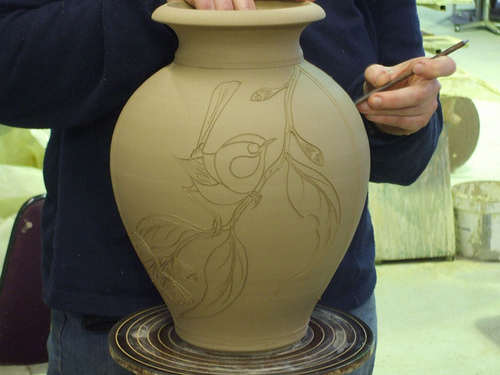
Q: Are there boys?
A: No, there are no boys.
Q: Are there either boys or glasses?
A: No, there are no boys or glasses.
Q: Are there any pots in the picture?
A: Yes, there is a pot.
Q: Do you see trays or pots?
A: Yes, there is a pot.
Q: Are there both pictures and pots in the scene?
A: No, there is a pot but no pictures.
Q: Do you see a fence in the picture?
A: No, there are no fences.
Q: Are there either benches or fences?
A: No, there are no fences or benches.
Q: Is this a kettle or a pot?
A: This is a pot.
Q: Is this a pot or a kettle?
A: This is a pot.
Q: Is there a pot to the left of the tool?
A: Yes, there is a pot to the left of the tool.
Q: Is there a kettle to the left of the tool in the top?
A: No, there is a pot to the left of the tool.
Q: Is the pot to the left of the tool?
A: Yes, the pot is to the left of the tool.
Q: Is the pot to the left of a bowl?
A: No, the pot is to the left of the tool.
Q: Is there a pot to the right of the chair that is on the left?
A: Yes, there is a pot to the right of the chair.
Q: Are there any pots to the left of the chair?
A: No, the pot is to the right of the chair.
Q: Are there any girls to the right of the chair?
A: No, there is a pot to the right of the chair.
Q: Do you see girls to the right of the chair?
A: No, there is a pot to the right of the chair.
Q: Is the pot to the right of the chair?
A: Yes, the pot is to the right of the chair.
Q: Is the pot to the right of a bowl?
A: No, the pot is to the right of the chair.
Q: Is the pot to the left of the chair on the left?
A: No, the pot is to the right of the chair.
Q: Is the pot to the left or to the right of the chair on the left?
A: The pot is to the right of the chair.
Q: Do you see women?
A: No, there are no women.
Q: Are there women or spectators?
A: No, there are no women or spectators.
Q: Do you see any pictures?
A: No, there are no pictures.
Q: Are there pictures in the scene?
A: No, there are no pictures.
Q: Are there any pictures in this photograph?
A: No, there are no pictures.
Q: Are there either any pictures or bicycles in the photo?
A: No, there are no pictures or bicycles.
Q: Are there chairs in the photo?
A: Yes, there is a chair.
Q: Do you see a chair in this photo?
A: Yes, there is a chair.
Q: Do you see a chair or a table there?
A: Yes, there is a chair.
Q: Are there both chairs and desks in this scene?
A: No, there is a chair but no desks.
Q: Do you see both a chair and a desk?
A: No, there is a chair but no desks.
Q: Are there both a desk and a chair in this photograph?
A: No, there is a chair but no desks.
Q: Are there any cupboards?
A: No, there are no cupboards.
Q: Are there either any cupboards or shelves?
A: No, there are no cupboards or shelves.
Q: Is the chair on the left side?
A: Yes, the chair is on the left of the image.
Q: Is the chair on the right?
A: No, the chair is on the left of the image.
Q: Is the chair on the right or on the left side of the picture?
A: The chair is on the left of the image.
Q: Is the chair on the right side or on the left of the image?
A: The chair is on the left of the image.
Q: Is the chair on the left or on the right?
A: The chair is on the left of the image.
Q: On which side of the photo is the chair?
A: The chair is on the left of the image.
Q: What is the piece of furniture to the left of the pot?
A: The piece of furniture is a chair.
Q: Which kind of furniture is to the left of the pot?
A: The piece of furniture is a chair.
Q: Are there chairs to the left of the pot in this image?
A: Yes, there is a chair to the left of the pot.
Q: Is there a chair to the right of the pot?
A: No, the chair is to the left of the pot.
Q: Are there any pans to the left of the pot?
A: No, there is a chair to the left of the pot.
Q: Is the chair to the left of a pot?
A: Yes, the chair is to the left of a pot.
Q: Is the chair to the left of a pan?
A: No, the chair is to the left of a pot.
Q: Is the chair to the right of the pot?
A: No, the chair is to the left of the pot.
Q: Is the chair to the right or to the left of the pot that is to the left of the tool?
A: The chair is to the left of the pot.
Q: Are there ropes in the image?
A: No, there are no ropes.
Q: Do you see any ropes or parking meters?
A: No, there are no ropes or parking meters.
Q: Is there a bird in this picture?
A: Yes, there is a bird.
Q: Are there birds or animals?
A: Yes, there is a bird.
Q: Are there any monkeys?
A: No, there are no monkeys.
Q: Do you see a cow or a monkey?
A: No, there are no monkeys or cows.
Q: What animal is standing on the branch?
A: The bird is standing on the branch.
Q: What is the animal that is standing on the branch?
A: The animal is a bird.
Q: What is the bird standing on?
A: The bird is standing on the branch.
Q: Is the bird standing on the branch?
A: Yes, the bird is standing on the branch.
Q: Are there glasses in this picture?
A: No, there are no glasses.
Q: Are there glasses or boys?
A: No, there are no glasses or boys.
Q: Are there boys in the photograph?
A: No, there are no boys.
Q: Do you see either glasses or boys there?
A: No, there are no boys or glasses.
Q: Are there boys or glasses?
A: No, there are no boys or glasses.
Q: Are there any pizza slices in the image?
A: No, there are no pizza slices.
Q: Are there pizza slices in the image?
A: No, there are no pizza slices.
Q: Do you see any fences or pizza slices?
A: No, there are no pizza slices or fences.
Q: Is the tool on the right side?
A: Yes, the tool is on the right of the image.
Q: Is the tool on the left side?
A: No, the tool is on the right of the image.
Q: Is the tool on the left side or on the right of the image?
A: The tool is on the right of the image.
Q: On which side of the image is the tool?
A: The tool is on the right of the image.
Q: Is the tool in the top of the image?
A: Yes, the tool is in the top of the image.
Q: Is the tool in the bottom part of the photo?
A: No, the tool is in the top of the image.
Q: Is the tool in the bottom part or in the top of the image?
A: The tool is in the top of the image.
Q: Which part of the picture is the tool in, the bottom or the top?
A: The tool is in the top of the image.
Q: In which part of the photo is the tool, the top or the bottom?
A: The tool is in the top of the image.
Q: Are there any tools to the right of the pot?
A: Yes, there is a tool to the right of the pot.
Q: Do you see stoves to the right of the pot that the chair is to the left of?
A: No, there is a tool to the right of the pot.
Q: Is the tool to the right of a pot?
A: Yes, the tool is to the right of a pot.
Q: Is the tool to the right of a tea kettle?
A: No, the tool is to the right of a pot.